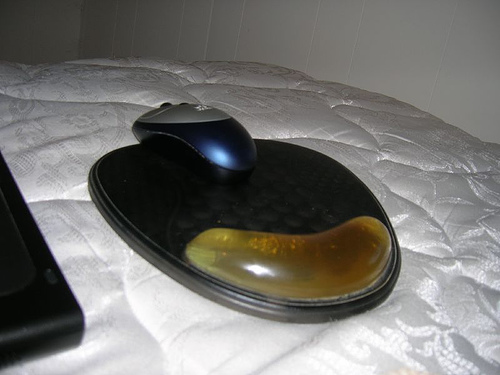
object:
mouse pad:
[87, 138, 401, 324]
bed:
[0, 59, 500, 375]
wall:
[405, 126, 442, 163]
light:
[141, 284, 404, 369]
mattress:
[452, 277, 496, 317]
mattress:
[226, 68, 258, 99]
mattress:
[69, 73, 111, 101]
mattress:
[142, 295, 222, 347]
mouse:
[131, 102, 258, 184]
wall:
[132, 1, 499, 123]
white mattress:
[2, 56, 499, 373]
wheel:
[179, 102, 190, 106]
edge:
[43, 294, 76, 330]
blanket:
[286, 74, 497, 261]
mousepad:
[196, 173, 337, 272]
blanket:
[0, 50, 500, 375]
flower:
[436, 186, 496, 265]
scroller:
[159, 102, 173, 108]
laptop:
[0, 149, 83, 359]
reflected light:
[229, 260, 279, 281]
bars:
[156, 4, 246, 55]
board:
[40, 253, 84, 348]